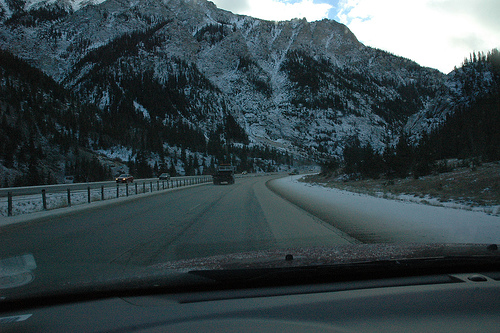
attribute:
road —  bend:
[4, 166, 340, 271]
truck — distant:
[198, 154, 247, 198]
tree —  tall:
[472, 49, 477, 67]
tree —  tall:
[487, 50, 492, 62]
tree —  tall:
[483, 52, 486, 62]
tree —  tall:
[476, 50, 481, 61]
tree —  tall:
[462, 60, 469, 69]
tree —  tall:
[452, 66, 458, 75]